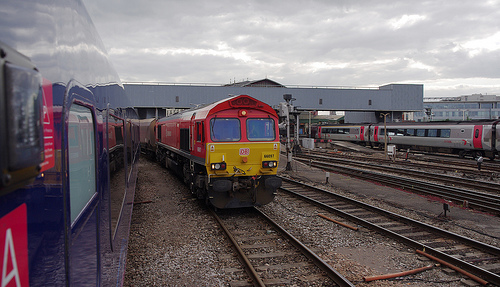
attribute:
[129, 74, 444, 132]
building — long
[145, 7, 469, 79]
clouds — white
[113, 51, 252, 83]
cloud — white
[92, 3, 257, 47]
cloud — white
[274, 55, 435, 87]
cloud — white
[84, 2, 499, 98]
sky — blue, overcast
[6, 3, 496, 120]
sky — very cloudy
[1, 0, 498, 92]
clouds — white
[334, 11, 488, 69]
clouds — white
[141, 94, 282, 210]
train — red, yellow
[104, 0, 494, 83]
clouds — white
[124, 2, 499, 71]
sky — blue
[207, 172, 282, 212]
bumpers — black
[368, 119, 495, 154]
car — silver, red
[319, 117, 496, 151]
train — grey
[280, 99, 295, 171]
pole — grey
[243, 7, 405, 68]
sky — blue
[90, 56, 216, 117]
sky — blue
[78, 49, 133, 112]
clouds — white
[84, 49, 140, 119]
sky — blue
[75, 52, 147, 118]
clouds — white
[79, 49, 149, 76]
sky — blue